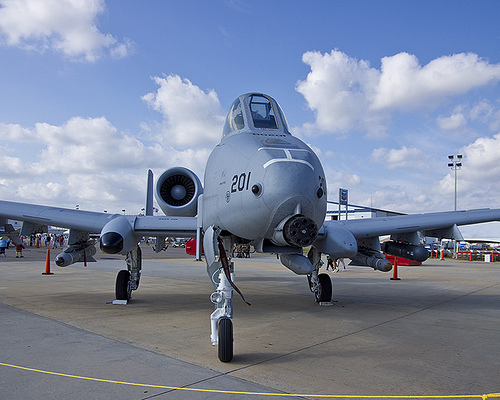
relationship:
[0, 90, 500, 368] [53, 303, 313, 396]
jet on turmac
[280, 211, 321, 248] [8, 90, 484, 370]
gun on front of plane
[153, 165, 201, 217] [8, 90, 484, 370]
engine near rear of plane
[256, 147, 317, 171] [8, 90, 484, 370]
lines on nose of plane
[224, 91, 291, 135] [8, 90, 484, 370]
cockpit of plane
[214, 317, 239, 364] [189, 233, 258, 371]
tire on gear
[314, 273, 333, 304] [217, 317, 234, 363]
plane wheel on tire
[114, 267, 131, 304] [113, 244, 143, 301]
tire on landing gear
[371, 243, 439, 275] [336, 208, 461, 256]
missle under wing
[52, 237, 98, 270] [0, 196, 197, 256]
missle under wing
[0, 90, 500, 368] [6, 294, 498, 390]
jet on tarmac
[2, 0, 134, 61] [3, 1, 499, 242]
cloud in sky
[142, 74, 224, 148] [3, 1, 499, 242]
cloud in sky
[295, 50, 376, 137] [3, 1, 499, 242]
cloud in sky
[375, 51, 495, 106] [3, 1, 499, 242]
cloud in sky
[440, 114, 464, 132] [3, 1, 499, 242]
cloud in sky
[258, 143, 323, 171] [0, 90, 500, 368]
lines on jet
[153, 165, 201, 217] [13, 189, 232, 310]
engine near tail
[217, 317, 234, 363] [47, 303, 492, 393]
tire on tarmac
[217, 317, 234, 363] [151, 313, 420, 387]
tire on tarmac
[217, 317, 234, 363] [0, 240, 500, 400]
tire on airport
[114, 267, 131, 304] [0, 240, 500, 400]
tire on airport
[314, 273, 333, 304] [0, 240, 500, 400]
plane wheel on airport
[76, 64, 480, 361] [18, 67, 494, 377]
jet in foreground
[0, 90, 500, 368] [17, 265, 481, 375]
jet on ground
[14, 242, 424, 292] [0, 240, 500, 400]
cones on airport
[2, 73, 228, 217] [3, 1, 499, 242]
clouds in sky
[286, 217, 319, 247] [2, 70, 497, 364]
gun in front of jet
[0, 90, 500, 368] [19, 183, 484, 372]
jet on airport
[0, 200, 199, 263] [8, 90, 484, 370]
wing of plane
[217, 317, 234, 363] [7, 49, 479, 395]
tire of plane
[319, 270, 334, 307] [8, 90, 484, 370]
plane wheel of plane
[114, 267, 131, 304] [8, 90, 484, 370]
tire of plane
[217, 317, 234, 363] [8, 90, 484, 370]
tire of plane